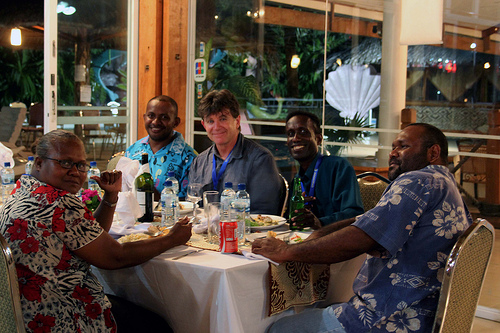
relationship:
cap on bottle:
[223, 180, 230, 188] [217, 178, 235, 231]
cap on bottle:
[235, 179, 248, 191] [230, 180, 251, 240]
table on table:
[88, 189, 366, 333] [81, 178, 312, 303]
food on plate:
[246, 213, 277, 228] [242, 213, 289, 230]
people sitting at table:
[4, 93, 484, 331] [95, 185, 367, 331]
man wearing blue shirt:
[324, 114, 449, 322] [345, 185, 457, 307]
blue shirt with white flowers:
[345, 185, 457, 307] [432, 199, 463, 229]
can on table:
[219, 218, 236, 253] [73, 188, 363, 331]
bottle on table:
[136, 155, 153, 222] [35, 167, 337, 322]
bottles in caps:
[188, 175, 294, 280] [209, 180, 286, 200]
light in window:
[288, 53, 305, 72] [229, 15, 383, 157]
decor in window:
[322, 62, 379, 125] [408, 47, 496, 128]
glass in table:
[203, 190, 219, 239] [90, 166, 375, 328]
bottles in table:
[220, 182, 236, 202] [114, 208, 309, 323]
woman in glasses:
[18, 139, 122, 326] [41, 153, 119, 184]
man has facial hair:
[251, 122, 474, 331] [386, 153, 406, 180]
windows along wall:
[190, 1, 390, 163] [1, 6, 497, 131]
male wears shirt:
[188, 89, 282, 216] [184, 139, 276, 213]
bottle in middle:
[135, 153, 154, 223] [104, 192, 209, 233]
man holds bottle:
[252, 104, 364, 256] [286, 172, 309, 230]